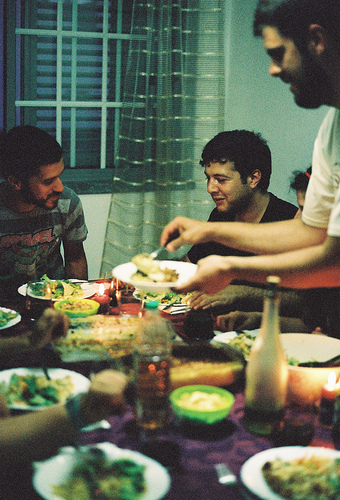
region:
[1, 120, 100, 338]
man with striped shirt at dinner table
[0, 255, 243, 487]
dinner table filled with food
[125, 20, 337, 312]
man serving food at dinner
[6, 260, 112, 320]
plate and bowl with salad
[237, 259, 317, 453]
bottle of oil on dinner table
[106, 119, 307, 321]
man waiting to be served dinner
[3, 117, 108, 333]
man with beard at dinner table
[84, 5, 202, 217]
window with sheer curtains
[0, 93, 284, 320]
two men having dinner together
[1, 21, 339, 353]
family having dinner together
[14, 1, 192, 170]
window with white panes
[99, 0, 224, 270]
curtain on side of window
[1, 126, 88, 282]
man in striped shirt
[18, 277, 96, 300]
food on white plate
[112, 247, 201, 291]
utensil under food on plate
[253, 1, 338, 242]
man in short sleeves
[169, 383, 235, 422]
food in green bowl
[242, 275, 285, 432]
bottle with top on table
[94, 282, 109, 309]
flame on top of candle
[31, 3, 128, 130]
closed shutter on window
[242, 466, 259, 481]
a white plate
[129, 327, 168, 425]
a bottle on the table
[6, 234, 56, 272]
logo on the shirt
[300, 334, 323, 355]
the bowl is white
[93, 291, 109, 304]
a candle on the table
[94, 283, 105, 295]
fire on the candle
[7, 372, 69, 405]
a salad in the bowl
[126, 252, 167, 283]
food in the dish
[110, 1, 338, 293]
A man preparing a plate of food.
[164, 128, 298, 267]
A young man seated at a table.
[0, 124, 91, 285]
A man in a striped shirt with a logo on the front listening intently to a young man seated next to him.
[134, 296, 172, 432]
A bottle of amber-colored liquid with a green lid.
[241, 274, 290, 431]
A bottle of wine.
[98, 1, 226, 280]
Sheer curtains with silvery stripes hanging in front of a window.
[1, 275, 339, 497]
A table full of food and drinks.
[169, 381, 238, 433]
A green bowl half full of a yellowish substance.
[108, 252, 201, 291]
A white plate which is having food placed upon it.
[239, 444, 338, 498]
A white plate, on the table, full of food.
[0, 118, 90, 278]
BLACK HAIRED MAN IN GREY STRIPED SHIRT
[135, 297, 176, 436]
PLASTIC BOTTLE OF LIQUID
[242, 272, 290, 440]
WINE BOTTLE LESS THAN HALF FULL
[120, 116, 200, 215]
TRANSPARENT DRAPERY WITH GOLD STRIPE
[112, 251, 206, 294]
PLATE WITH FOOD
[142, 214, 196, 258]
HAND SERVING FOOD ON PLATE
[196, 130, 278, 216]
MAN WITH BLACK HAIR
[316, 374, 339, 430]
CANDLE ON THE TABLE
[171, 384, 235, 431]
GREEN BOWL OF FOOD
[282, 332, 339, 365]
WHITE PLATE ON TABLE